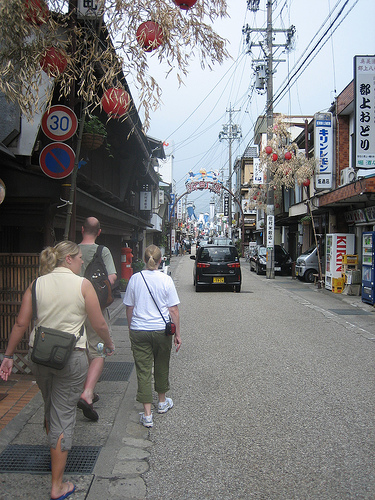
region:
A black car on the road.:
[192, 244, 242, 289]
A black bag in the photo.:
[32, 328, 74, 362]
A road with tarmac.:
[247, 321, 283, 408]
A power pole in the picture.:
[263, 191, 279, 269]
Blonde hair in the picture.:
[33, 241, 75, 265]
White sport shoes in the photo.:
[155, 396, 172, 412]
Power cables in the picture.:
[309, 25, 335, 53]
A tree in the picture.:
[79, 29, 101, 82]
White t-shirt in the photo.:
[119, 269, 175, 327]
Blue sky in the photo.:
[346, 25, 368, 43]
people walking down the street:
[18, 197, 203, 461]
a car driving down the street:
[170, 211, 292, 446]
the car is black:
[181, 226, 273, 340]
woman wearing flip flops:
[34, 436, 96, 498]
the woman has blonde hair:
[23, 229, 90, 273]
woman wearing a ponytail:
[12, 221, 94, 281]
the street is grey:
[195, 297, 351, 451]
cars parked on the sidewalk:
[256, 235, 343, 282]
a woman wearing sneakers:
[121, 361, 194, 451]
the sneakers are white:
[114, 383, 196, 433]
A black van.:
[194, 241, 240, 292]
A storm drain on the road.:
[1, 440, 102, 476]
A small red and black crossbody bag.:
[135, 269, 176, 334]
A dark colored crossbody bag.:
[29, 274, 91, 368]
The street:
[12, 235, 372, 495]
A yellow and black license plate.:
[213, 276, 225, 282]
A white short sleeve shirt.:
[123, 269, 178, 329]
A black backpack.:
[83, 246, 113, 306]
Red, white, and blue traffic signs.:
[41, 107, 77, 182]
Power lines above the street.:
[157, 5, 373, 196]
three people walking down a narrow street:
[0, 200, 371, 499]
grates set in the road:
[2, 314, 133, 477]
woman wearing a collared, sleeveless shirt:
[26, 264, 87, 348]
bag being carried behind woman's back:
[27, 274, 86, 370]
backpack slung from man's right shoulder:
[80, 215, 118, 306]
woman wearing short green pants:
[129, 327, 176, 404]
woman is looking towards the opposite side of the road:
[39, 235, 370, 276]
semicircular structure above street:
[162, 165, 247, 276]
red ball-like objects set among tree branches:
[0, 2, 230, 133]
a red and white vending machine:
[322, 232, 355, 291]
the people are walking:
[1, 204, 186, 494]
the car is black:
[190, 235, 255, 310]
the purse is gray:
[26, 321, 78, 375]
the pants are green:
[129, 328, 170, 399]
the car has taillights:
[196, 257, 245, 274]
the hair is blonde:
[39, 249, 56, 268]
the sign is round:
[41, 101, 77, 141]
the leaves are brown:
[94, 47, 125, 72]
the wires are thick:
[293, 45, 320, 73]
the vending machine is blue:
[354, 230, 370, 300]